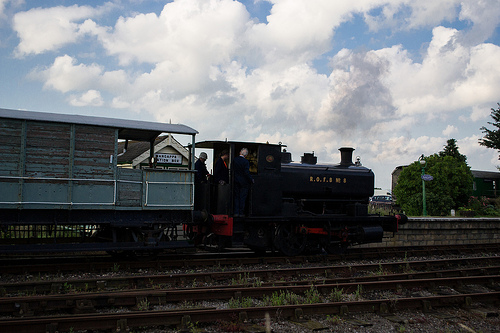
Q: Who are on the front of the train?
A: Train engineers.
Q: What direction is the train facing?
A: Right.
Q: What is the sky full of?
A: Clouds.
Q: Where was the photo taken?
A: Near train tracks.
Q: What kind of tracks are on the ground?
A: Train tracks.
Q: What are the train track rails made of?
A: Metal.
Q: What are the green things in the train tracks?
A: Weeds.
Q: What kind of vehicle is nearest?
A: A train.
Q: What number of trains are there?
A: One.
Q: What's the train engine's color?
A: Black.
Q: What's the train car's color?
A: Gray.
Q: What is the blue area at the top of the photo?
A: The sky.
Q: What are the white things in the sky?
A: Clouds.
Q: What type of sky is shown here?
A: A partly cloudy sky.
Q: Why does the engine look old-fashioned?
A: It has a steam stack.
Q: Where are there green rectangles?
A: On the side of the train car.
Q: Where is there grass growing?
A: In between the tracks.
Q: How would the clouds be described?
A: As puffy.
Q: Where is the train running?
A: On the tracks.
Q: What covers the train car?
A: A roof.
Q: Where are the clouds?
A: In the sky.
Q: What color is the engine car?
A: Black, red, and yellow.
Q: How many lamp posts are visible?
A: One.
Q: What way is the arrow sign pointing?
A: Right.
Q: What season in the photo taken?
A: Summer.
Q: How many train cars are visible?
A: Two.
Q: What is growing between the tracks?
A: Grass.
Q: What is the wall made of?
A: Brick.